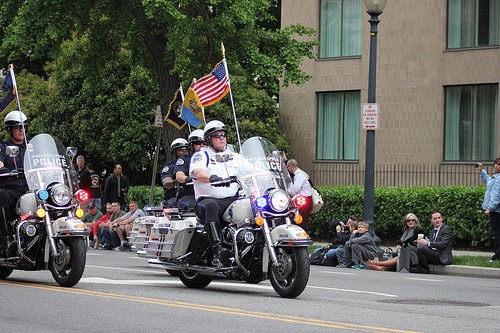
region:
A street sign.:
[362, 101, 379, 133]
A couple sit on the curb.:
[398, 210, 450, 277]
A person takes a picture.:
[475, 158, 499, 230]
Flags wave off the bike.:
[166, 40, 232, 127]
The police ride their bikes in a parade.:
[136, 118, 319, 301]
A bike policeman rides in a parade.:
[1, 110, 86, 287]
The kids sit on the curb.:
[331, 215, 373, 272]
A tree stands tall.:
[7, 8, 149, 104]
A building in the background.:
[279, 5, 493, 165]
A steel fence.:
[327, 165, 457, 180]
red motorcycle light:
[71, 187, 91, 202]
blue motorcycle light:
[33, 188, 51, 201]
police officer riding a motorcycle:
[3, 57, 90, 287]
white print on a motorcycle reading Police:
[30, 155, 65, 165]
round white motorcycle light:
[266, 185, 292, 210]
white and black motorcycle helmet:
[201, 119, 231, 139]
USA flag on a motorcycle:
[191, 40, 251, 153]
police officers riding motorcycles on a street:
[1, 108, 313, 299]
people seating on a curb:
[309, 208, 455, 273]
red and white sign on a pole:
[360, 100, 379, 131]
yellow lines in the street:
[47, 283, 377, 331]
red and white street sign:
[358, 99, 380, 131]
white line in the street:
[398, 274, 443, 284]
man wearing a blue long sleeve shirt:
[472, 168, 499, 212]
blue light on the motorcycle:
[254, 192, 269, 210]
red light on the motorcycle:
[293, 192, 310, 212]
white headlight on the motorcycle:
[268, 185, 291, 214]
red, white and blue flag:
[189, 58, 231, 108]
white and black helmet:
[2, 108, 30, 131]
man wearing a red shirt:
[92, 213, 111, 236]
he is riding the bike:
[188, 182, 233, 239]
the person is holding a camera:
[471, 159, 498, 182]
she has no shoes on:
[364, 255, 386, 276]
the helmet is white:
[198, 117, 226, 135]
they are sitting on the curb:
[328, 217, 454, 271]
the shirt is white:
[201, 156, 228, 175]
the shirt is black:
[2, 152, 29, 176]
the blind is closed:
[326, 105, 356, 151]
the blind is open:
[455, 96, 498, 133]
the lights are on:
[38, 184, 92, 206]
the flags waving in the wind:
[161, 50, 242, 133]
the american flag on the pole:
[197, 54, 229, 108]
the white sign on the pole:
[363, 101, 378, 131]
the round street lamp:
[363, 0, 384, 17]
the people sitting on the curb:
[306, 208, 463, 273]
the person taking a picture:
[471, 154, 498, 264]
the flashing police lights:
[247, 187, 312, 219]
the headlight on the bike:
[51, 179, 71, 204]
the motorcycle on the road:
[4, 101, 96, 293]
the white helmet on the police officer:
[3, 105, 30, 125]